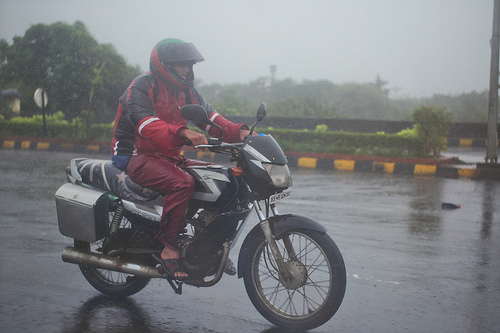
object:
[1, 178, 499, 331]
road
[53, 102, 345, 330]
motorcycle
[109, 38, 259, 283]
man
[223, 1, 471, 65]
sky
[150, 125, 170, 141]
red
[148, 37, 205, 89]
helmet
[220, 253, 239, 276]
sandals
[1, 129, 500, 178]
curb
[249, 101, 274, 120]
sideview mirrors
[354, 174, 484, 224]
rain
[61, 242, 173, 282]
exhaust pipe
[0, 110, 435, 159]
hedge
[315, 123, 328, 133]
leaves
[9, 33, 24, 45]
leaves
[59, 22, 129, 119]
trees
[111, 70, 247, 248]
suit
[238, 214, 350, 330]
front wheel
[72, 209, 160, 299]
rear wheel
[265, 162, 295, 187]
headlight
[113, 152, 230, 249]
pants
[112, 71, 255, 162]
jacket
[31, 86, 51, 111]
sign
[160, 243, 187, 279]
foot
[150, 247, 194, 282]
sandal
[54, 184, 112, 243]
storage compartment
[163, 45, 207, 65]
visor